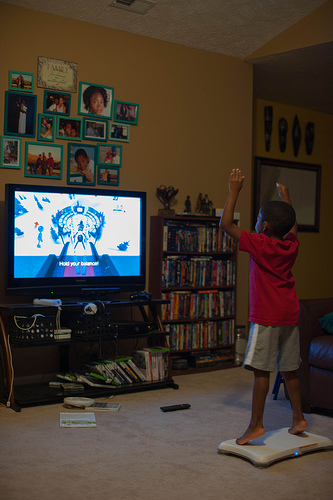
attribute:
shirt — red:
[232, 241, 284, 330]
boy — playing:
[225, 172, 312, 441]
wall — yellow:
[0, 0, 253, 378]